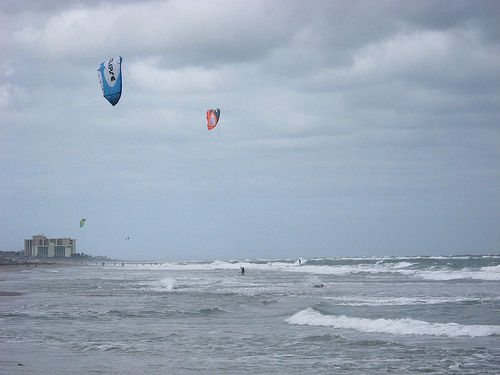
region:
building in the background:
[24, 234, 75, 256]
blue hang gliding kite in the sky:
[100, 56, 126, 109]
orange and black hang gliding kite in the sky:
[204, 107, 220, 132]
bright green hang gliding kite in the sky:
[79, 214, 88, 225]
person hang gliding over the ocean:
[237, 265, 243, 276]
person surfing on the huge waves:
[297, 257, 303, 262]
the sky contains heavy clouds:
[0, 0, 496, 257]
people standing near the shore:
[25, 259, 164, 271]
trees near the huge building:
[71, 251, 111, 260]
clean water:
[0, 258, 498, 373]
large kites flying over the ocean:
[85, 45, 285, 300]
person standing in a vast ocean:
[162, 235, 382, 316]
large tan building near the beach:
[10, 220, 116, 290]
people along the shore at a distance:
[60, 250, 185, 276]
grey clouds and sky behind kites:
[70, 40, 250, 157]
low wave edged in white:
[255, 291, 485, 361]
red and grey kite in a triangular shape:
[186, 85, 251, 182]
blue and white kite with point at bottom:
[85, 45, 135, 120]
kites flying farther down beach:
[50, 205, 182, 251]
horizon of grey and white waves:
[167, 241, 492, 279]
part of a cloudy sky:
[284, 50, 414, 142]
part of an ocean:
[295, 262, 395, 338]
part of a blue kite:
[92, 53, 127, 105]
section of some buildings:
[21, 227, 79, 259]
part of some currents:
[352, 245, 434, 284]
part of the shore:
[16, 257, 53, 304]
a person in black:
[231, 262, 253, 279]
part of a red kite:
[196, 96, 220, 131]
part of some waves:
[178, 326, 318, 364]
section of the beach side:
[3, 255, 38, 267]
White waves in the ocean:
[281, 295, 496, 357]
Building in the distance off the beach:
[1, 222, 80, 279]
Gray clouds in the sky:
[238, 2, 486, 216]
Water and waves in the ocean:
[1, 266, 238, 367]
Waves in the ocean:
[333, 238, 495, 363]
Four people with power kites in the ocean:
[68, 49, 309, 288]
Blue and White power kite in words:
[88, 43, 135, 122]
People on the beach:
[4, 251, 172, 277]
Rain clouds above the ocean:
[39, 3, 458, 48]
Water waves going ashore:
[25, 273, 237, 365]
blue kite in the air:
[66, 50, 138, 128]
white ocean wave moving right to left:
[283, 294, 496, 351]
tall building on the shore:
[17, 220, 92, 275]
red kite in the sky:
[197, 105, 234, 147]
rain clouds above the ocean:
[5, 0, 490, 119]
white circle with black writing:
[102, 52, 119, 92]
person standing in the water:
[208, 250, 280, 287]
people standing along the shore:
[10, 256, 176, 276]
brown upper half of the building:
[19, 229, 96, 247]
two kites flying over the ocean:
[42, 37, 269, 187]